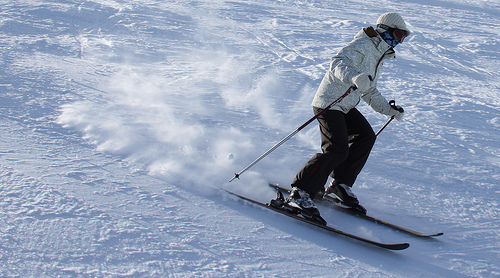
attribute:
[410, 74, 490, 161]
snow — white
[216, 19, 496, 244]
man — skiing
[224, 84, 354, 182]
ski pole — black, silver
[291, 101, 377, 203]
ski pants — black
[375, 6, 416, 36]
hat — white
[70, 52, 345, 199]
snow — flying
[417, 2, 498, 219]
snow — white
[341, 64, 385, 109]
glove — white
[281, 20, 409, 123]
jacket — white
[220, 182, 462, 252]
skis — black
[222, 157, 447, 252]
skies — black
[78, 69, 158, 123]
snow — bright, white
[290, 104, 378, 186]
pants — black, wrinkled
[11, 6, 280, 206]
tracks — long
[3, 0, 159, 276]
snow — thick, white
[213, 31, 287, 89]
snow — white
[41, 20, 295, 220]
snow dust — flying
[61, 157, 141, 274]
snow — white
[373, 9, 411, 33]
hat — white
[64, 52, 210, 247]
snow — white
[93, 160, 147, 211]
snow — white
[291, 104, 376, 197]
pants — black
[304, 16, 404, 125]
jacket — white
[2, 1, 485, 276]
snow — white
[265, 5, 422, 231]
person — skiing